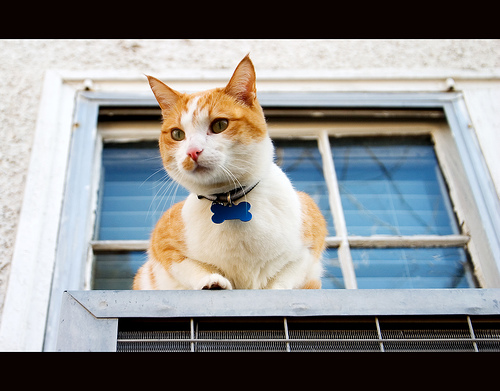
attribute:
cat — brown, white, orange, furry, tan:
[133, 52, 330, 292]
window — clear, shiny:
[90, 134, 476, 288]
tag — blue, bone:
[209, 201, 252, 223]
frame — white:
[3, 67, 499, 290]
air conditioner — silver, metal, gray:
[54, 290, 500, 353]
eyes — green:
[172, 118, 228, 141]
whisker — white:
[143, 163, 272, 214]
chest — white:
[187, 194, 307, 288]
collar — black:
[197, 181, 260, 199]